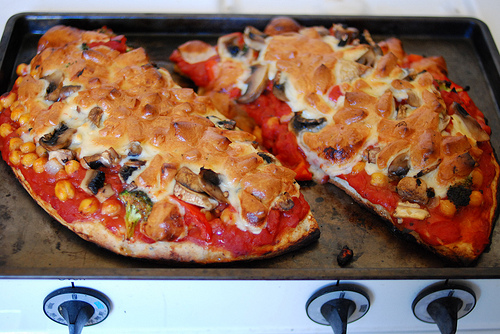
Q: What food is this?
A: Pizza.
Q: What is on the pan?
A: Pizza sliced in half.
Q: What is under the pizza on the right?
A: Pair of black dials.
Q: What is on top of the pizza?
A: Melted cheese.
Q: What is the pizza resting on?
A: Baking sheet.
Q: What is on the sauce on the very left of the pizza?
A: Corn.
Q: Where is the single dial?
A: Under the left side of pizza.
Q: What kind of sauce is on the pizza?
A: Red tomato sauce.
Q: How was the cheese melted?
A: Heat of the oven.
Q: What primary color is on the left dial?
A: Blue.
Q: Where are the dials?
A: On the stove.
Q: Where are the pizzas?
A: On a tray.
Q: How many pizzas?
A: 2.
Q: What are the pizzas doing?
A: Sitting on a tray.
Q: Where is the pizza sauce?
A: On the pizza.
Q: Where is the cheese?
A: On the pizza.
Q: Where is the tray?
A: On the stove.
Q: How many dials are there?
A: 3.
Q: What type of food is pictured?
A: Pizza.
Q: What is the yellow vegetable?
A: Corn.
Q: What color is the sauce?
A: Red.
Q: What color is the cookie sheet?
A: Brown.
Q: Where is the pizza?
A: On top of the oven.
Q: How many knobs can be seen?
A: 3.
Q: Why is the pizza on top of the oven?
A: It is done cooking.